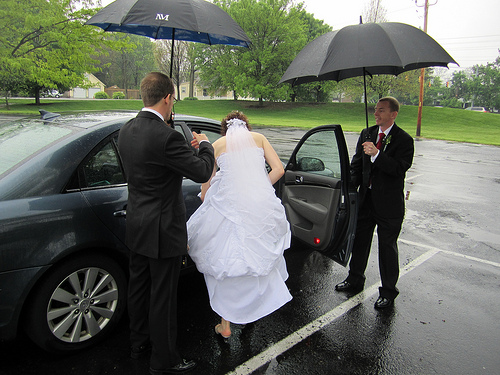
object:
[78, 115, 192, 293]
passenger door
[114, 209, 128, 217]
handle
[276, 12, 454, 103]
umbrella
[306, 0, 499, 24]
clouds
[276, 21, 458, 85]
top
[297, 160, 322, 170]
mirror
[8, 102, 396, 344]
car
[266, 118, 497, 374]
parking lot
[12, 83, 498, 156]
area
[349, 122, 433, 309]
suit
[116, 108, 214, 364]
suit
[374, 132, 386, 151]
red tie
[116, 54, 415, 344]
groomsmen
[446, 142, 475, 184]
ground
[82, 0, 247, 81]
umbrella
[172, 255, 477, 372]
white line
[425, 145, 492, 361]
parking lot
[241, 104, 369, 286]
door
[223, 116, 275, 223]
veil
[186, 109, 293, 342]
woman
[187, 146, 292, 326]
white dress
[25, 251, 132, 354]
wheel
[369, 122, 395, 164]
shirt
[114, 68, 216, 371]
man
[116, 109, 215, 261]
suit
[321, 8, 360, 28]
sky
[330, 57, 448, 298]
man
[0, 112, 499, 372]
parking lot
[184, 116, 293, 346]
bride